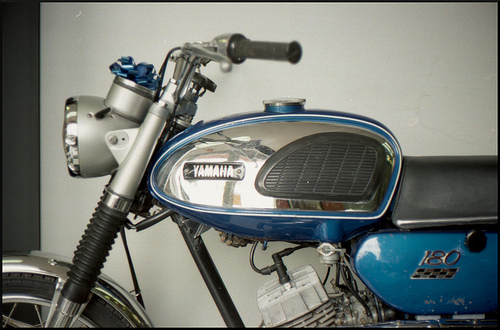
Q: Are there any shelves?
A: No, there are no shelves.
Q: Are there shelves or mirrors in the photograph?
A: No, there are no shelves or mirrors.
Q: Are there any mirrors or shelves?
A: No, there are no shelves or mirrors.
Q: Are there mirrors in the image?
A: No, there are no mirrors.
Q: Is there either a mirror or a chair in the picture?
A: No, there are no mirrors or chairs.